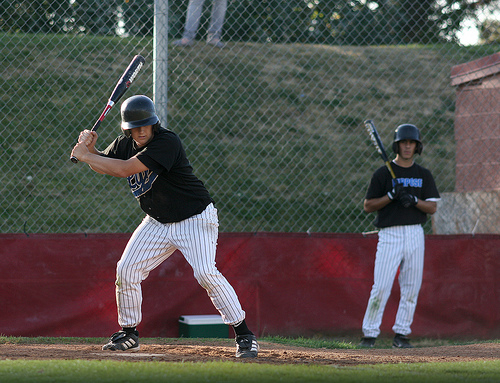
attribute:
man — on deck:
[68, 95, 266, 361]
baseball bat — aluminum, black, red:
[66, 48, 154, 165]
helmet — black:
[113, 91, 163, 125]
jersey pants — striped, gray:
[116, 201, 245, 332]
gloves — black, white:
[388, 179, 416, 205]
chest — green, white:
[173, 308, 235, 339]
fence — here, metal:
[1, 3, 498, 234]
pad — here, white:
[91, 346, 172, 357]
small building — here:
[445, 51, 499, 197]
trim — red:
[2, 227, 500, 334]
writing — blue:
[395, 175, 434, 192]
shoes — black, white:
[358, 333, 413, 352]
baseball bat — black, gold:
[360, 115, 412, 205]